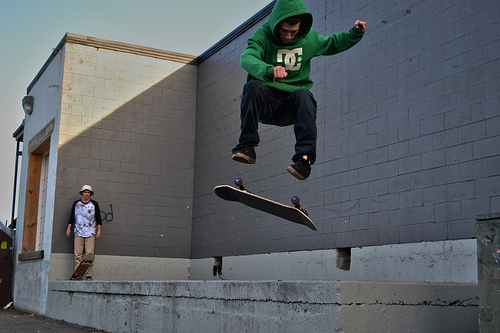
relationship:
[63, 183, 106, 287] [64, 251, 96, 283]
man with skateboard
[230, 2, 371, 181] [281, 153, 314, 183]
man with shoes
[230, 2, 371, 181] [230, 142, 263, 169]
man with shoes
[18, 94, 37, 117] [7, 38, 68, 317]
fixture on wall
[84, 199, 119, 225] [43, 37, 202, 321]
graffiti on wall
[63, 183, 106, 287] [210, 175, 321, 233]
man jumping with skateboard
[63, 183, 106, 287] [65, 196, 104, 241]
man with shirt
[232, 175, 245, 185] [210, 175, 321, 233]
wheel of skateboard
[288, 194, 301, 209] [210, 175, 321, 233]
wheel on skateboard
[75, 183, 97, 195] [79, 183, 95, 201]
hat on head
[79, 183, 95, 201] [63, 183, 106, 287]
head of man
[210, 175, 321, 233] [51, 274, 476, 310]
skateboard on floor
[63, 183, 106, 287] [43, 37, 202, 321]
man by wall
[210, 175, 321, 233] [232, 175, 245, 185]
skateboard has wheel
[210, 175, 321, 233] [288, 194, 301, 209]
skateboard has wheel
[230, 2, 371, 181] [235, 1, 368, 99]
man wearing sweatshirt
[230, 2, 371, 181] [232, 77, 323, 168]
man wearing pants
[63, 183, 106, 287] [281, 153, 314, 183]
man wearing shoes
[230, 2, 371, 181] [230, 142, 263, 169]
man wearing shoes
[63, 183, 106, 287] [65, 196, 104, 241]
man wearing shirt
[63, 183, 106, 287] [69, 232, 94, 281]
man wearing pants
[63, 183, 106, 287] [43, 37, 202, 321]
man against wall